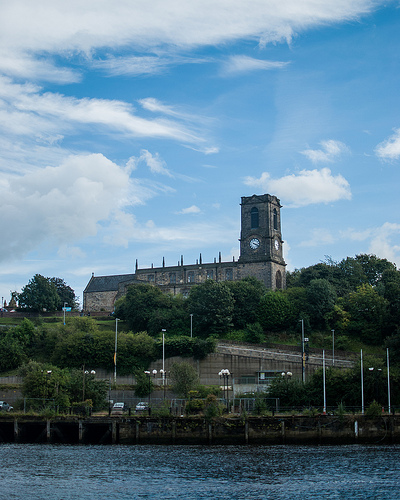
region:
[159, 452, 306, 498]
dark clear water in lake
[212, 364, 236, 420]
black and white street lights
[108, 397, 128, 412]
car parked in lot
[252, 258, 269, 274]
brick walls of building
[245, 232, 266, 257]
clock on brick building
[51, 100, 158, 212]
white clouds in blue sky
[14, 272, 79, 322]
big green tree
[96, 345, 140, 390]
plants growing on wall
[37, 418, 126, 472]
bridge that water goes under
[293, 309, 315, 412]
large light posts in parking lot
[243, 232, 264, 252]
Clock on the building.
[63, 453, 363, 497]
The water is blue.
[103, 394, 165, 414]
Cars in the parking lot.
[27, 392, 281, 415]
The fence is grey.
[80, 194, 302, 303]
Building is made of brick.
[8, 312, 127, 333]
The grass is green.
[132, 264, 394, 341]
The trees are green.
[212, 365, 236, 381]
White lights on poles.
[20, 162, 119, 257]
Clouds in the sky.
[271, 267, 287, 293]
Arch on the side of the building.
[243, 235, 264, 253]
clock in tower of brown building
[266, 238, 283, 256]
clock in tower of brown building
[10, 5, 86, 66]
white clouds against blue sky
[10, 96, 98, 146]
white clouds against blue sky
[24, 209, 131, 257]
white clouds against blue sky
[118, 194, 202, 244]
white clouds against blue sky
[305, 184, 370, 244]
white clouds against blue sky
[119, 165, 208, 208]
white clouds against blue sky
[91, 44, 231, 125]
white clouds against blue sky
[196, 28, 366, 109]
white clouds against blue sky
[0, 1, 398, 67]
wispy white clouds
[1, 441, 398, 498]
blue rippling water in front of car park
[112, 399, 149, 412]
2 light colored cars in parking lot by water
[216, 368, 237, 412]
outdoor lamp post in parking lot by water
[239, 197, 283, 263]
clock tower attached to stone building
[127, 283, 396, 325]
green hedges and trees by stone building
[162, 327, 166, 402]
tall lamp post in parking lot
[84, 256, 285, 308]
stone building with six visible windows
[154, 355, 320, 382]
stone wall next to parking area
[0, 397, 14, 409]
light colored car in parking lot by water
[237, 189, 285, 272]
tall stone clock tower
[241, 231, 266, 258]
clock on side of tower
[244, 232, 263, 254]
clock that reads twenty past three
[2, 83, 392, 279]
white clouds in blue sky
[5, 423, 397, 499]
calmly flowing river water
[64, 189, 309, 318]
large old stone structure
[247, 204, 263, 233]
arched window on stone tower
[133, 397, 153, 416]
white car in parking lot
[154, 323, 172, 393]
tall metal light post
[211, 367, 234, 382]
white globes atop lamp post